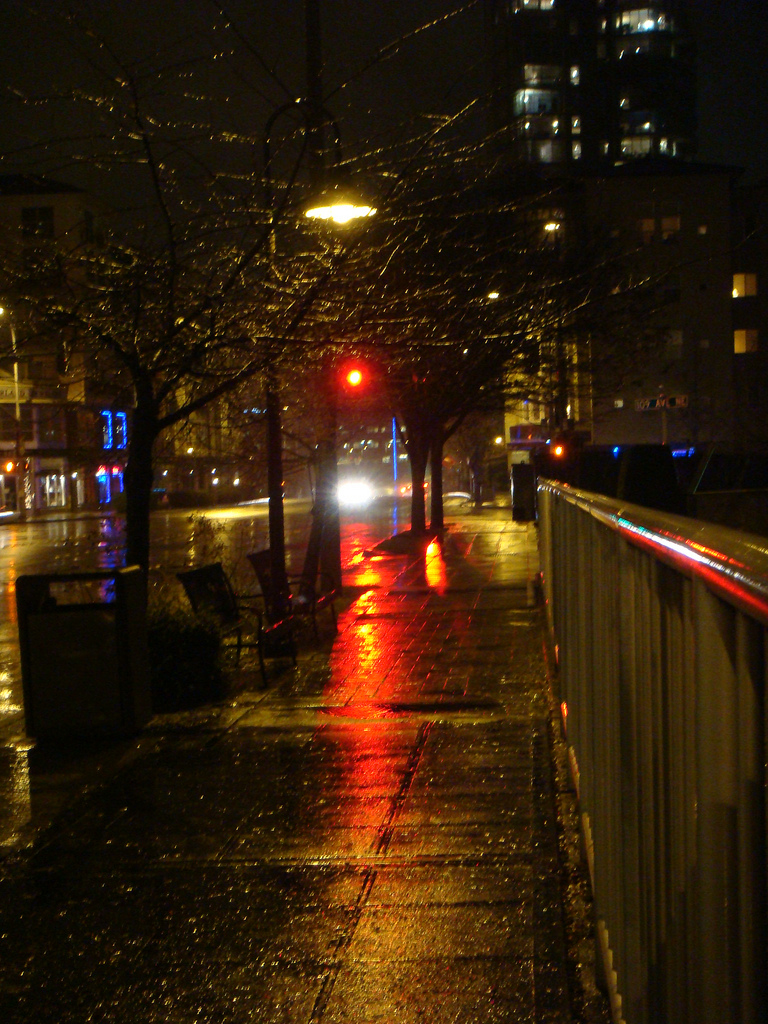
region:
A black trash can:
[20, 560, 150, 735]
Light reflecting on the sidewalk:
[334, 538, 412, 833]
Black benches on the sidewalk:
[178, 547, 343, 677]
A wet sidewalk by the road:
[9, 483, 570, 1020]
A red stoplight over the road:
[336, 356, 370, 394]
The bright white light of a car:
[332, 470, 381, 507]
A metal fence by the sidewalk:
[535, 479, 766, 1022]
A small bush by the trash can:
[133, 593, 236, 697]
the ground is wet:
[10, 441, 644, 1022]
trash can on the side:
[0, 533, 172, 776]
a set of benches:
[162, 533, 360, 710]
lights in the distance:
[300, 467, 403, 528]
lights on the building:
[81, 394, 143, 512]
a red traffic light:
[315, 346, 381, 396]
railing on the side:
[501, 455, 766, 1022]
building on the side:
[481, 270, 755, 472]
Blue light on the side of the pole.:
[609, 438, 622, 458]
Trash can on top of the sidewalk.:
[6, 551, 154, 751]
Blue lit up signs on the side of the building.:
[81, 390, 140, 458]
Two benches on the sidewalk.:
[176, 547, 333, 650]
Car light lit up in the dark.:
[322, 456, 377, 518]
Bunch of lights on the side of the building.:
[513, 34, 701, 167]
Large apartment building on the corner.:
[460, 1, 765, 461]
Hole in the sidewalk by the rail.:
[388, 670, 526, 746]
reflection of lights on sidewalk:
[317, 543, 440, 862]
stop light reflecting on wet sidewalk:
[295, 534, 434, 839]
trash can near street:
[7, 542, 181, 785]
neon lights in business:
[79, 389, 139, 517]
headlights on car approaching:
[324, 461, 407, 535]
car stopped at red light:
[289, 313, 394, 530]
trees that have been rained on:
[119, 260, 377, 471]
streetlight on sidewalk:
[243, 80, 398, 755]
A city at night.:
[0, 293, 753, 1012]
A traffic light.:
[333, 366, 380, 405]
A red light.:
[330, 359, 378, 391]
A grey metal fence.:
[535, 468, 764, 1012]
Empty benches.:
[174, 540, 338, 674]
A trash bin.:
[22, 578, 142, 762]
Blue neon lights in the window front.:
[93, 408, 137, 514]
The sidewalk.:
[93, 450, 630, 1022]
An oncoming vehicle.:
[290, 442, 430, 507]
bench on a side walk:
[176, 538, 370, 665]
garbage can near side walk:
[14, 555, 150, 751]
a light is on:
[300, 205, 374, 219]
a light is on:
[346, 360, 363, 386]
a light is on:
[554, 442, 562, 457]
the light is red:
[4, 455, 18, 473]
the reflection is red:
[340, 528, 393, 829]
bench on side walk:
[179, 558, 268, 673]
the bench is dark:
[250, 551, 331, 636]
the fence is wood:
[539, 485, 763, 1022]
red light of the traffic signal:
[329, 346, 370, 394]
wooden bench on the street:
[190, 573, 290, 659]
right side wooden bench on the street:
[257, 554, 327, 614]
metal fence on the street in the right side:
[564, 525, 749, 895]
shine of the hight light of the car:
[342, 477, 374, 506]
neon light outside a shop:
[89, 404, 123, 448]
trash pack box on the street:
[9, 577, 140, 730]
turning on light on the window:
[720, 268, 757, 297]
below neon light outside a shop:
[87, 461, 124, 497]